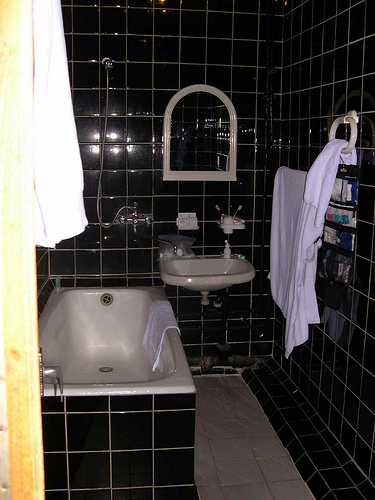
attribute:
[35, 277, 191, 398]
bath tub — white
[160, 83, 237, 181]
frame — white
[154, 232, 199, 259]
bag — plastic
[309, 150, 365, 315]
organizer — black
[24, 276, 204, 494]
bathtub — white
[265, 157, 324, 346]
bath towel — white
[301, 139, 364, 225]
hand towel — white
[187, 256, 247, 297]
basin — sink, white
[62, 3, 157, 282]
tiled — black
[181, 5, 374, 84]
tiled — black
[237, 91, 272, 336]
tiled — black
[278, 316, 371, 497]
tiled — black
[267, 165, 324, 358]
towel — white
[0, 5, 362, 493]
bathroom — ugly